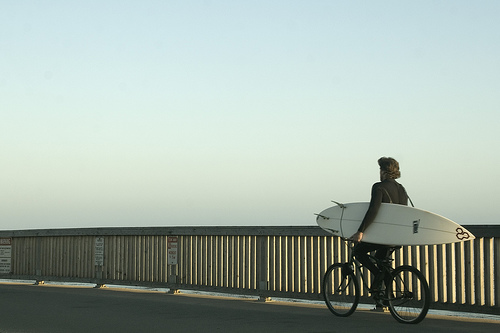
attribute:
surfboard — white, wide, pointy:
[316, 202, 476, 244]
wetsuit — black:
[351, 181, 409, 296]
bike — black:
[322, 240, 432, 324]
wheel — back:
[322, 262, 360, 317]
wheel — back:
[385, 266, 431, 325]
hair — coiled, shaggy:
[378, 157, 401, 182]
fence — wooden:
[0, 225, 499, 316]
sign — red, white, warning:
[165, 235, 180, 266]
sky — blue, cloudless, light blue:
[1, 1, 500, 230]